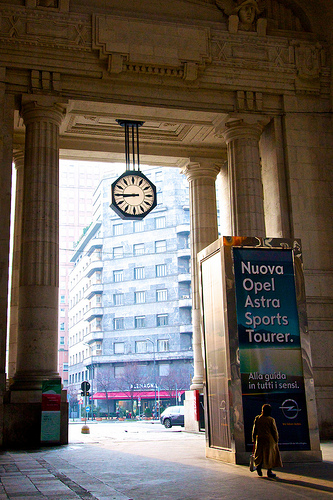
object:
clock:
[110, 170, 157, 217]